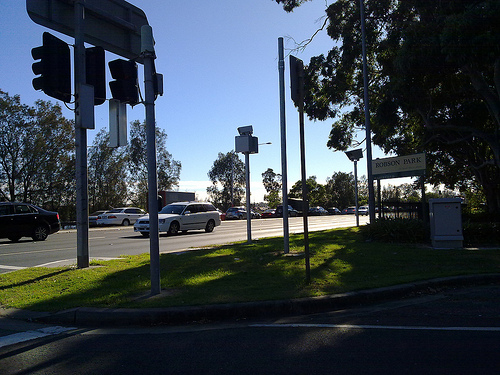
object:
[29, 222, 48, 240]
tire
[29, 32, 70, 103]
traffic light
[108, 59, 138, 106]
traffic light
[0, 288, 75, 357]
intersection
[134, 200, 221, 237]
car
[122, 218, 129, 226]
black tire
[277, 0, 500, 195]
tree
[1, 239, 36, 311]
intersection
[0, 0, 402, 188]
sky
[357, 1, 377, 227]
pole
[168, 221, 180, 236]
tire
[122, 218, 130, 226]
tire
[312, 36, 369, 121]
leaves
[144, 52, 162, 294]
pole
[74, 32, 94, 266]
pole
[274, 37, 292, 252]
pole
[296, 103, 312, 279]
pole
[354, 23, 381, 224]
pole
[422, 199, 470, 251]
ground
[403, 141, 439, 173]
ground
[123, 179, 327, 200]
cloud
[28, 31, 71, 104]
light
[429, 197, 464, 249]
box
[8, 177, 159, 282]
on road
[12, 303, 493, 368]
road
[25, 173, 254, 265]
road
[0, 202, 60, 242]
car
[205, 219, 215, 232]
tire